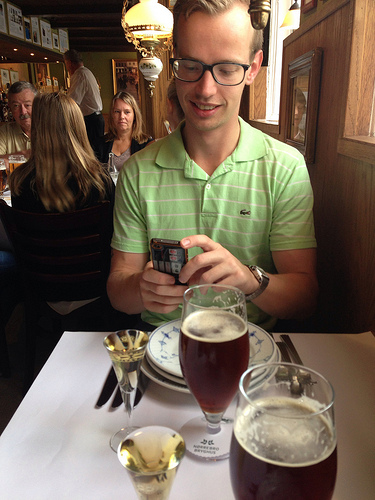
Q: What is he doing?
A: Texting.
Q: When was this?
A: Daytime.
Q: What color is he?
A: White.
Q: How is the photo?
A: Clear.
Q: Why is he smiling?
A: He is happy.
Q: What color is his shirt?
A: Green.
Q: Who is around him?
A: People.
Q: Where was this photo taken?
A: At a restaurant.